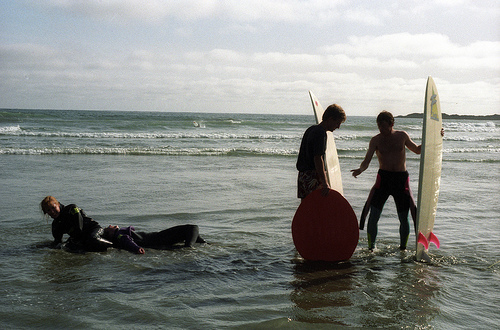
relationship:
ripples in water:
[144, 263, 259, 308] [121, 137, 222, 195]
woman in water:
[99, 211, 192, 271] [121, 137, 222, 195]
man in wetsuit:
[295, 101, 332, 172] [53, 206, 123, 271]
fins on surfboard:
[408, 222, 444, 262] [413, 85, 440, 186]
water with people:
[121, 137, 222, 195] [28, 182, 210, 281]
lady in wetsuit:
[39, 190, 104, 245] [53, 206, 123, 271]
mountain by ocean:
[411, 104, 443, 127] [0, 103, 500, 152]